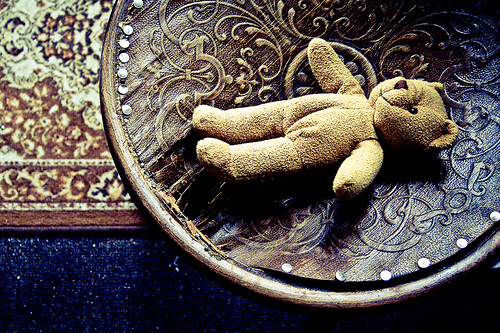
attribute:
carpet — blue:
[70, 261, 237, 326]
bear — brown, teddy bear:
[235, 43, 450, 172]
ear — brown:
[426, 117, 459, 151]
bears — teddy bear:
[188, 133, 277, 173]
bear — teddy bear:
[182, 30, 462, 205]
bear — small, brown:
[181, 39, 456, 197]